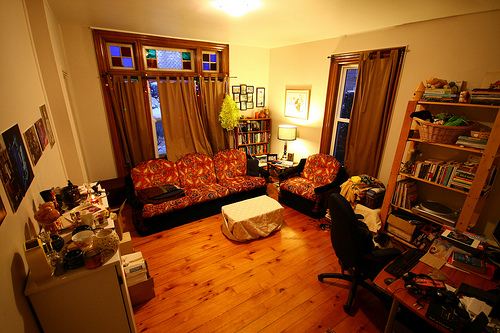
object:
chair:
[318, 193, 403, 313]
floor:
[108, 165, 423, 332]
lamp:
[277, 124, 298, 160]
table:
[247, 152, 307, 187]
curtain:
[343, 49, 402, 177]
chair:
[278, 153, 349, 219]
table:
[221, 194, 284, 242]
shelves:
[379, 77, 500, 250]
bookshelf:
[379, 101, 500, 251]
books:
[411, 158, 463, 187]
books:
[391, 178, 418, 209]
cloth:
[228, 208, 269, 217]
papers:
[120, 251, 147, 280]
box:
[131, 287, 155, 306]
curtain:
[106, 75, 155, 169]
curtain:
[156, 76, 214, 163]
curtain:
[200, 76, 231, 154]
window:
[148, 79, 168, 159]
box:
[128, 274, 154, 297]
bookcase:
[233, 118, 272, 169]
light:
[214, 0, 256, 17]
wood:
[112, 179, 433, 331]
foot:
[318, 273, 352, 281]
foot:
[343, 280, 358, 313]